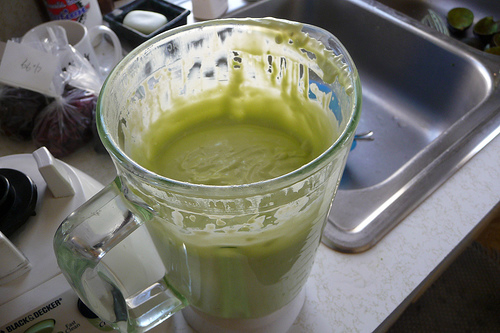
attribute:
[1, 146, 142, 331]
blender base — white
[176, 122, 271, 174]
cream — green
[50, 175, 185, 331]
handle — glass, clear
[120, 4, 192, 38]
soapholder — black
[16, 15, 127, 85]
mug — coffee mug, white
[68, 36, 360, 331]
blender — clear, white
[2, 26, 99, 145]
bags — clear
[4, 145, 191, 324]
base — white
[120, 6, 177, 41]
soap — white, bar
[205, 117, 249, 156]
paste — yellow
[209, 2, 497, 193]
sink — steel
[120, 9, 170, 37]
soap — white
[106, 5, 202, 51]
container — black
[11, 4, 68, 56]
mug — white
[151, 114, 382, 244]
cream — green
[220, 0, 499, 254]
sink — steel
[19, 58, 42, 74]
4.99 — black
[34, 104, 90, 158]
items — dark, red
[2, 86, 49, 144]
items — dark, red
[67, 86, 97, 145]
items — dark, red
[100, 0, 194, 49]
dish — black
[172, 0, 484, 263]
sink — stainless steel, metal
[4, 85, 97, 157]
food — red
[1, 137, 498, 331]
counter — white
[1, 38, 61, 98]
tag — white